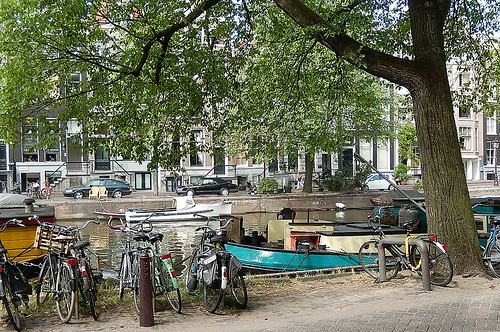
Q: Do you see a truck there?
A: No, there are no trucks.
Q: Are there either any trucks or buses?
A: No, there are no trucks or buses.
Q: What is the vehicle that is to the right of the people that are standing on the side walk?
A: The vehicle is a car.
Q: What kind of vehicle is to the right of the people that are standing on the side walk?
A: The vehicle is a car.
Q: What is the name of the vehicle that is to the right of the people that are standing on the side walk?
A: The vehicle is a car.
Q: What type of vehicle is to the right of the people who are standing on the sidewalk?
A: The vehicle is a car.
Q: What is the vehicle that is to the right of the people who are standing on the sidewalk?
A: The vehicle is a car.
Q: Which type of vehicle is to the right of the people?
A: The vehicle is a car.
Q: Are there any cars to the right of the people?
A: Yes, there is a car to the right of the people.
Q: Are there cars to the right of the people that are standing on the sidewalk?
A: Yes, there is a car to the right of the people.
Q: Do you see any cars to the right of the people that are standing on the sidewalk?
A: Yes, there is a car to the right of the people.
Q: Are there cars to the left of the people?
A: No, the car is to the right of the people.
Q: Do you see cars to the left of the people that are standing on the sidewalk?
A: No, the car is to the right of the people.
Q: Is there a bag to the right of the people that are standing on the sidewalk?
A: No, there is a car to the right of the people.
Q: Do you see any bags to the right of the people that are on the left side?
A: No, there is a car to the right of the people.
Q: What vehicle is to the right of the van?
A: The vehicle is a car.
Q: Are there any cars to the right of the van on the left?
A: Yes, there is a car to the right of the van.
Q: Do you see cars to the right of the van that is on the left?
A: Yes, there is a car to the right of the van.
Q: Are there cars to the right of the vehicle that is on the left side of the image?
A: Yes, there is a car to the right of the van.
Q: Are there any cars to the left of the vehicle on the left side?
A: No, the car is to the right of the van.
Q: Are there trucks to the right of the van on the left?
A: No, there is a car to the right of the van.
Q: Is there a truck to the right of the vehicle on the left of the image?
A: No, there is a car to the right of the van.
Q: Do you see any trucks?
A: No, there are no trucks.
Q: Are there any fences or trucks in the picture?
A: No, there are no trucks or fences.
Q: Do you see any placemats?
A: No, there are no placemats.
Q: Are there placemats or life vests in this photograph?
A: No, there are no placemats or life vests.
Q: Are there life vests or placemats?
A: No, there are no placemats or life vests.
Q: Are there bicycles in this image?
A: Yes, there is a bicycle.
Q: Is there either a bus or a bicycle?
A: Yes, there is a bicycle.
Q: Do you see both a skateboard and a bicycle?
A: No, there is a bicycle but no skateboards.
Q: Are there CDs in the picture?
A: No, there are no cds.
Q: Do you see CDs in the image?
A: No, there are no cds.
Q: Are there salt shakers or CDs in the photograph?
A: No, there are no CDs or salt shakers.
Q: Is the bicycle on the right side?
A: Yes, the bicycle is on the right of the image.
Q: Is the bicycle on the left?
A: No, the bicycle is on the right of the image.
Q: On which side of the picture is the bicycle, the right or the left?
A: The bicycle is on the right of the image.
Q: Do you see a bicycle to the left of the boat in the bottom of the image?
A: No, the bicycle is to the right of the boat.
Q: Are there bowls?
A: No, there are no bowls.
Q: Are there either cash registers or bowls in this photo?
A: No, there are no bowls or cash registers.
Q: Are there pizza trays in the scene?
A: No, there are no pizza trays.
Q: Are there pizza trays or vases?
A: No, there are no pizza trays or vases.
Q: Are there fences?
A: No, there are no fences.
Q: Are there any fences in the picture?
A: No, there are no fences.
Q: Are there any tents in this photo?
A: No, there are no tents.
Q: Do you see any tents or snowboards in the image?
A: No, there are no tents or snowboards.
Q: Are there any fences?
A: No, there are no fences.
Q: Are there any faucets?
A: No, there are no faucets.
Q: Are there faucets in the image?
A: No, there are no faucets.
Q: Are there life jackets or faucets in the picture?
A: No, there are no faucets or life jackets.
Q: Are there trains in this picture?
A: No, there are no trains.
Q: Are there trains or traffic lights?
A: No, there are no trains or traffic lights.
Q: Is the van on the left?
A: Yes, the van is on the left of the image.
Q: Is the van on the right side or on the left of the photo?
A: The van is on the left of the image.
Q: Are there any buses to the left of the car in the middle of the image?
A: No, there is a van to the left of the car.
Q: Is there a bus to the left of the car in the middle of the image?
A: No, there is a van to the left of the car.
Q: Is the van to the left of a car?
A: Yes, the van is to the left of a car.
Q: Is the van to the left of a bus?
A: No, the van is to the left of a car.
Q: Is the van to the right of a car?
A: No, the van is to the left of a car.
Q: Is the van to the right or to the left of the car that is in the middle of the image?
A: The van is to the left of the car.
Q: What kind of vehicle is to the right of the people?
A: The vehicle is a van.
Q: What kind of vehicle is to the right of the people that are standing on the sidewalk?
A: The vehicle is a van.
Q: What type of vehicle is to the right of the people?
A: The vehicle is a van.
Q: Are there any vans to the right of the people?
A: Yes, there is a van to the right of the people.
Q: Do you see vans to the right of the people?
A: Yes, there is a van to the right of the people.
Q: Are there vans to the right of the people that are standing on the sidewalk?
A: Yes, there is a van to the right of the people.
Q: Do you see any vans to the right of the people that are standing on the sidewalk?
A: Yes, there is a van to the right of the people.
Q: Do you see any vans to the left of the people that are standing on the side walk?
A: No, the van is to the right of the people.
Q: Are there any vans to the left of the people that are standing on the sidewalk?
A: No, the van is to the right of the people.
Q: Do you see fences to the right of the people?
A: No, there is a van to the right of the people.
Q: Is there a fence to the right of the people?
A: No, there is a van to the right of the people.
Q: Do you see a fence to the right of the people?
A: No, there is a van to the right of the people.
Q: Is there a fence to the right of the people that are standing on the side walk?
A: No, there is a van to the right of the people.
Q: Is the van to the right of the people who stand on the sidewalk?
A: Yes, the van is to the right of the people.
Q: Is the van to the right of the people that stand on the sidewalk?
A: Yes, the van is to the right of the people.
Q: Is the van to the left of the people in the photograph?
A: No, the van is to the right of the people.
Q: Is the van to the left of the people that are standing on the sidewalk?
A: No, the van is to the right of the people.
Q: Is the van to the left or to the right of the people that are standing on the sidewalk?
A: The van is to the right of the people.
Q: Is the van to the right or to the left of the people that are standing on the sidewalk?
A: The van is to the right of the people.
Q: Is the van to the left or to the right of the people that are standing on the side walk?
A: The van is to the right of the people.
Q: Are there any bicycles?
A: Yes, there is a bicycle.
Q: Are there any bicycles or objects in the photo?
A: Yes, there is a bicycle.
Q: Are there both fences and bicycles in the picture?
A: No, there is a bicycle but no fences.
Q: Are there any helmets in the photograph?
A: No, there are no helmets.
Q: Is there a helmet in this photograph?
A: No, there are no helmets.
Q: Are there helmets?
A: No, there are no helmets.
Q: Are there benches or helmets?
A: No, there are no helmets or benches.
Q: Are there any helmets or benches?
A: No, there are no helmets or benches.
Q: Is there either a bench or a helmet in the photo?
A: No, there are no helmets or benches.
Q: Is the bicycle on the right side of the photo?
A: Yes, the bicycle is on the right of the image.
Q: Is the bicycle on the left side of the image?
A: No, the bicycle is on the right of the image.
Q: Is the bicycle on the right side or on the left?
A: The bicycle is on the right of the image.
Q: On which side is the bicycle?
A: The bicycle is on the right of the image.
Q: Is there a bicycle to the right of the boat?
A: Yes, there is a bicycle to the right of the boat.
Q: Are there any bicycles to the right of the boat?
A: Yes, there is a bicycle to the right of the boat.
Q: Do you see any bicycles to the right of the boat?
A: Yes, there is a bicycle to the right of the boat.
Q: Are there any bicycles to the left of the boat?
A: No, the bicycle is to the right of the boat.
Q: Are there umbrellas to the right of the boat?
A: No, there is a bicycle to the right of the boat.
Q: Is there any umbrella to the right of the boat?
A: No, there is a bicycle to the right of the boat.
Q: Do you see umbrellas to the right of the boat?
A: No, there is a bicycle to the right of the boat.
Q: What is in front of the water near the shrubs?
A: The bicycle is in front of the water.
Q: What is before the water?
A: The bicycle is in front of the water.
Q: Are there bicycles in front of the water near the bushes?
A: Yes, there is a bicycle in front of the water.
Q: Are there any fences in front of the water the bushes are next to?
A: No, there is a bicycle in front of the water.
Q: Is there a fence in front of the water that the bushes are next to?
A: No, there is a bicycle in front of the water.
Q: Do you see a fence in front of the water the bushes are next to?
A: No, there is a bicycle in front of the water.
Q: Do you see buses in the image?
A: No, there are no buses.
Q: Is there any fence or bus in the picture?
A: No, there are no buses or fences.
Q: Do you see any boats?
A: Yes, there is a boat.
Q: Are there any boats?
A: Yes, there is a boat.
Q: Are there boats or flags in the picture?
A: Yes, there is a boat.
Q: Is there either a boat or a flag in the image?
A: Yes, there is a boat.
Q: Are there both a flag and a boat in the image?
A: No, there is a boat but no flags.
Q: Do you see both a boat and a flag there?
A: No, there is a boat but no flags.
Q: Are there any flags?
A: No, there are no flags.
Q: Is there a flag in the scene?
A: No, there are no flags.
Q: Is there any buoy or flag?
A: No, there are no flags or buoys.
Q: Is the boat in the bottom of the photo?
A: Yes, the boat is in the bottom of the image.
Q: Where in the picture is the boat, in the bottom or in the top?
A: The boat is in the bottom of the image.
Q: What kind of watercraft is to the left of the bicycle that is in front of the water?
A: The watercraft is a boat.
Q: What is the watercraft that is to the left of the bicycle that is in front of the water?
A: The watercraft is a boat.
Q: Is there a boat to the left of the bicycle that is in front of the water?
A: Yes, there is a boat to the left of the bicycle.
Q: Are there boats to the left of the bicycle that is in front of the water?
A: Yes, there is a boat to the left of the bicycle.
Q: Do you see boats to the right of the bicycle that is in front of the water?
A: No, the boat is to the left of the bicycle.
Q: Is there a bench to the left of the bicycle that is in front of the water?
A: No, there is a boat to the left of the bicycle.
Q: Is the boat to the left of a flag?
A: No, the boat is to the left of the bicycle.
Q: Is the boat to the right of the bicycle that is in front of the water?
A: No, the boat is to the left of the bicycle.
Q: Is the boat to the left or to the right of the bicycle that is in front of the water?
A: The boat is to the left of the bicycle.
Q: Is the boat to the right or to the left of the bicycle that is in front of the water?
A: The boat is to the left of the bicycle.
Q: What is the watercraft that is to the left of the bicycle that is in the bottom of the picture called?
A: The watercraft is a boat.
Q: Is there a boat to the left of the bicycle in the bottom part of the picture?
A: Yes, there is a boat to the left of the bicycle.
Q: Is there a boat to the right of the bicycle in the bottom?
A: No, the boat is to the left of the bicycle.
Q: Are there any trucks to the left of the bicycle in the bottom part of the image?
A: No, there is a boat to the left of the bicycle.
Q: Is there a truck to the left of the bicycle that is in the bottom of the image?
A: No, there is a boat to the left of the bicycle.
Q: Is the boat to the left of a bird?
A: No, the boat is to the left of a bicycle.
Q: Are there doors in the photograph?
A: Yes, there is a door.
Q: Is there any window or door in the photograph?
A: Yes, there is a door.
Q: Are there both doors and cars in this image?
A: Yes, there are both a door and a car.